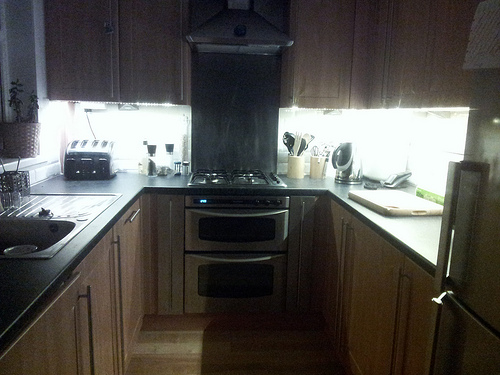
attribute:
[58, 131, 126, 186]
toaster — black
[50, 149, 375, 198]
counter — black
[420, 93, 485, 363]
refrigerator — stainless steel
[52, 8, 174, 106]
cupboards — wood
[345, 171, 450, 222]
cutting board — tan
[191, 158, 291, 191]
stove — gas, black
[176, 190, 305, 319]
oven — stainless steel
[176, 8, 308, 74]
range hood — stainless steel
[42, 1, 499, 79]
cabinets — wooden, closed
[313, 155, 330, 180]
holder — wooden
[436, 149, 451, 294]
handle — silver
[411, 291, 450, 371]
handle — silver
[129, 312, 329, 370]
floor — wooden